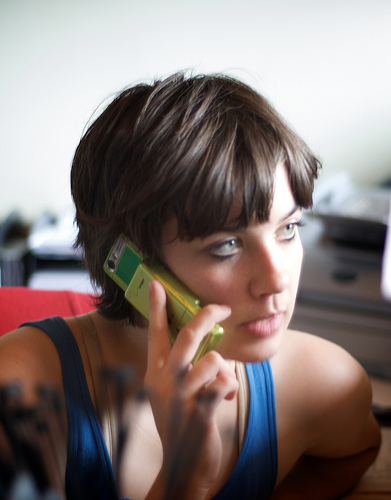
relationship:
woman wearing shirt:
[58, 71, 362, 453] [14, 307, 304, 493]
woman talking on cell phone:
[0, 67, 382, 500] [103, 232, 225, 367]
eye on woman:
[205, 238, 241, 255] [43, 59, 326, 431]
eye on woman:
[277, 223, 295, 239] [35, 37, 347, 439]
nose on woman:
[247, 239, 290, 299] [58, 71, 362, 453]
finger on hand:
[206, 360, 255, 404] [129, 288, 251, 466]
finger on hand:
[170, 292, 224, 365] [88, 265, 256, 461]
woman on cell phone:
[0, 67, 382, 500] [103, 232, 225, 367]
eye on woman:
[196, 237, 242, 255] [26, 74, 347, 467]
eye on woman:
[279, 209, 308, 247] [58, 71, 362, 453]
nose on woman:
[239, 239, 285, 312] [37, 53, 370, 468]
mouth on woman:
[224, 307, 297, 334] [24, 46, 383, 476]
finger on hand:
[200, 373, 239, 416] [125, 258, 279, 471]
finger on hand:
[186, 336, 243, 385] [117, 265, 253, 461]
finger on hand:
[166, 304, 232, 376] [137, 277, 250, 462]